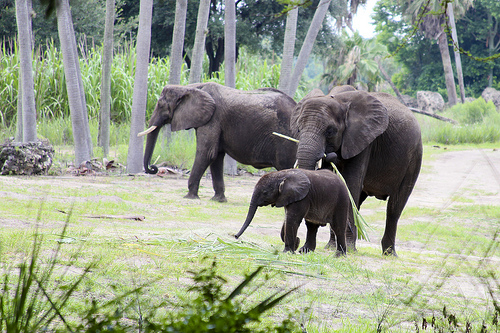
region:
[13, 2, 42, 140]
tall brown tree trunk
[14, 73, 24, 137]
tall brown tree trunk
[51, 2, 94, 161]
tall brown tree trunk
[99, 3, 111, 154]
tall brown tree trunk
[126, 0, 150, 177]
tall brown tree trunk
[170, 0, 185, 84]
tall brown tree trunk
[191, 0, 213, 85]
tall brown tree trunk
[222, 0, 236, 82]
tall brown tree trunk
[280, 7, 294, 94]
tall brown tree trunk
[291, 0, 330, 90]
tall brown tree trunk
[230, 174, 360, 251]
A grey elephant in the field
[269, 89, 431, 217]
A grey elephant in the field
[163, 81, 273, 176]
A grey elephant in the field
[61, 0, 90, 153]
A tall tree stem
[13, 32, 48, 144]
A tall tree stem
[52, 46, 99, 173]
A tall tree stem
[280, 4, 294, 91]
A tall tree stem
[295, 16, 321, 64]
A tall tree stem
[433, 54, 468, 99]
A tall tree stem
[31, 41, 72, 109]
A green maize field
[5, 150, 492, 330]
flat ground with stripes of grass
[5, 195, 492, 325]
plants with spiky or oval leaves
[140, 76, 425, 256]
adults and baby walking across ground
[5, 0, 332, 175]
line of gray tree trunks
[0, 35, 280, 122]
light-green plants on tall stalks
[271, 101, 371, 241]
elephant carrying long curved stalk in mouth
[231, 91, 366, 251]
baby elephant walking in front of adult elephant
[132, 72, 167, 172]
curled tip of trunk below tusk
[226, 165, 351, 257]
baby elephant with front bent knee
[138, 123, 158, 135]
tusk of the elephant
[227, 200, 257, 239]
trunk of the elephant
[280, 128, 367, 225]
elephant is carrying plant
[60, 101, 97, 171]
trunk of hte tree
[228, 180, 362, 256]
the elephant is a baby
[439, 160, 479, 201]
dirt on the ground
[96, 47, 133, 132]
bushes behind the trees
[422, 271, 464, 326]
branches on the bush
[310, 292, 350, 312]
patches of the grass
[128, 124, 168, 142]
Elephant has large white tusk.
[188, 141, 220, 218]
Elephant has large gray leg.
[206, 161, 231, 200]
Elephant has large gray leg.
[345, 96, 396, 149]
Elephant has large gray ear.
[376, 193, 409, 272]
Elephant has large gray back leg.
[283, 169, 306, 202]
Elephant has large gray ear.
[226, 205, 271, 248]
Elephant has long trunk.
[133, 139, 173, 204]
Elephant is carrying something in it's trunk.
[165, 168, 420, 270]
Elephants are walking in grassy field.